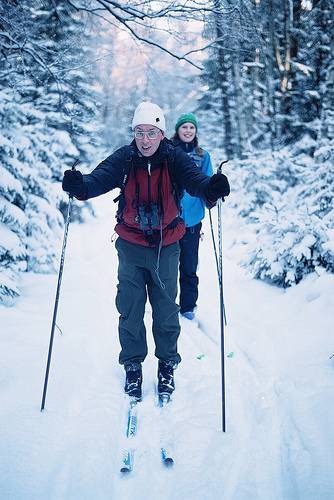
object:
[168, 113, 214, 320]
woman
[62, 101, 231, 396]
skier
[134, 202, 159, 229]
binoculars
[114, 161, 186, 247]
red vest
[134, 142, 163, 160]
neck